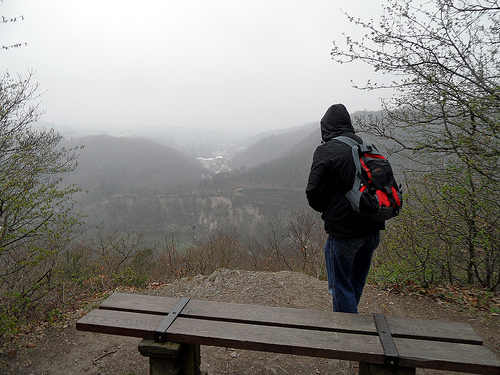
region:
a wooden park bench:
[74, 281, 497, 373]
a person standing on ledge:
[303, 98, 401, 315]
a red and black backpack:
[346, 136, 406, 224]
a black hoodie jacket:
[304, 99, 385, 239]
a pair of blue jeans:
[320, 231, 377, 312]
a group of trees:
[349, 2, 491, 283]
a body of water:
[86, 228, 198, 254]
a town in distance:
[203, 135, 240, 172]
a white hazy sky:
[8, 3, 495, 131]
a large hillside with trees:
[96, 190, 286, 253]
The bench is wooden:
[74, 280, 357, 374]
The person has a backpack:
[326, 129, 448, 269]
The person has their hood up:
[315, 86, 401, 190]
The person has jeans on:
[318, 220, 422, 341]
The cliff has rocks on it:
[153, 238, 323, 315]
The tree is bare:
[0, 77, 120, 346]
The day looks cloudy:
[178, 119, 312, 258]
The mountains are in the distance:
[76, 94, 278, 198]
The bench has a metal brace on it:
[118, 282, 248, 362]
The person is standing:
[286, 95, 413, 317]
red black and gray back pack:
[337, 143, 398, 258]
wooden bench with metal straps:
[2, 299, 449, 354]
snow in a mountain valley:
[168, 140, 252, 192]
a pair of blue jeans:
[295, 202, 389, 338]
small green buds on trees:
[376, 121, 494, 327]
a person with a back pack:
[296, 122, 390, 304]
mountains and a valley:
[59, 124, 280, 276]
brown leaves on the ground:
[0, 235, 150, 367]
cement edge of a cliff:
[129, 224, 323, 304]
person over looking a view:
[106, 134, 420, 361]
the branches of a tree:
[409, 41, 462, 101]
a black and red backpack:
[351, 130, 410, 233]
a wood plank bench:
[77, 277, 385, 371]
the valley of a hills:
[179, 119, 251, 188]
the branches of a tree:
[10, 111, 50, 179]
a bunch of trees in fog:
[190, 199, 285, 251]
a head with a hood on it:
[314, 99, 361, 140]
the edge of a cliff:
[174, 260, 296, 290]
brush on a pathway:
[6, 268, 71, 345]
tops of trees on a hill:
[100, 126, 162, 159]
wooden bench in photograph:
[82, 261, 480, 373]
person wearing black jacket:
[307, 82, 397, 284]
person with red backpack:
[284, 84, 399, 228]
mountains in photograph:
[45, 77, 315, 182]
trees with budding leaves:
[338, 17, 469, 294]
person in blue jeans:
[312, 220, 403, 331]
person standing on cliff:
[107, 234, 471, 329]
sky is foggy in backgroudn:
[71, 97, 321, 227]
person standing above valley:
[100, 78, 411, 236]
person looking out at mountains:
[255, 74, 379, 236]